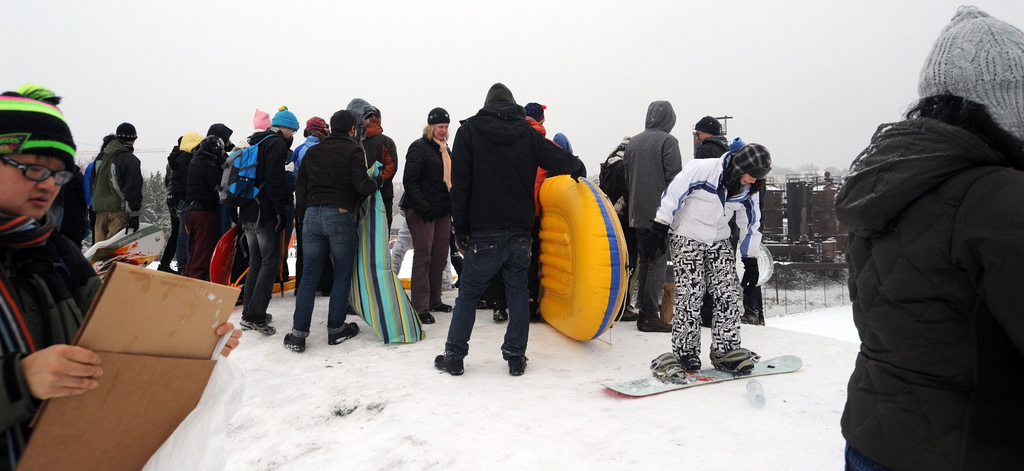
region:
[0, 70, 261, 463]
a boy holding cardboard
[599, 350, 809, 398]
the white snowboard the person is on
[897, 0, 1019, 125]
the gray hat of the person on the right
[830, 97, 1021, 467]
the black coat of the person on the right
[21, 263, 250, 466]
the cardboard the person is holding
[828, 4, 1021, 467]
the person furthest to the right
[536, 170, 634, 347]
the yellow inflatable the person is holding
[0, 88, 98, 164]
the green striped hat of the person on the right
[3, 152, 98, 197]
glasses are worn by the person on the right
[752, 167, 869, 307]
the buildings in the background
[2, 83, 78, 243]
the head of a man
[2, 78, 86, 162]
the hat of a man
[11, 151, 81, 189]
the glasses of a man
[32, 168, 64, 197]
the nose of a man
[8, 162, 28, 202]
the cheek of a man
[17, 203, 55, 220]
the chin of a man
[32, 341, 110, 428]
the right hand of a man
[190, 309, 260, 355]
the left hand of a man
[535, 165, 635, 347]
inflatable raft is yellow and blue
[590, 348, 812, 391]
snowboard is white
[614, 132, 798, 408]
person on a white snowboard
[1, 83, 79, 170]
hat is green, black, and red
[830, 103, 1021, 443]
coat is dark green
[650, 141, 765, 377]
person wearing black and white pants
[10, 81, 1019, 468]
people are all on top of the hill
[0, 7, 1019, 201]
sky is gray and foggy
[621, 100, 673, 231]
coat is gray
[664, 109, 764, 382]
person wearing a white and blue coat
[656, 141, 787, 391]
a person is standing up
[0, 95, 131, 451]
a person is standing up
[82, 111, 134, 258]
a person is standing up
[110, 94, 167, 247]
a person is standing up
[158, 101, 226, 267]
a person is standing up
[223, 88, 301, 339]
a person is standing up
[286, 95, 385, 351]
a person is standing up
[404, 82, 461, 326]
a person is standing up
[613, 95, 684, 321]
a person is standing up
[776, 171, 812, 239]
a building in a city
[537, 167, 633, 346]
yellow and blue blow up sled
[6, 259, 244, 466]
tan piece of cardboard box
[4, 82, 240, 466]
man in black glasses looking at cardboard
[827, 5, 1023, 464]
person in black jacket and gray cap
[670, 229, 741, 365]
pair of black and white patterned pants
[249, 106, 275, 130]
young child wearing pink cap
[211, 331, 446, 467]
deep footprints in the white snow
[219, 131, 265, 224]
blue backpack with black strap and trim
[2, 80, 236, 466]
man looking at cardboard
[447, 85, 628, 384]
man holding yellow sled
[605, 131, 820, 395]
boy on snow board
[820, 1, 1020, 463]
girl wearing knit beanie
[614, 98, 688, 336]
man wearing gray coat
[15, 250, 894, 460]
snow on the ground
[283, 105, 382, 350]
girl wearing black coat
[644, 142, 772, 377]
man wearing white coat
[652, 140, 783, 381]
man wearing plaid hat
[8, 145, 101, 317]
boy wearing eye glasses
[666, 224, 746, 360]
black and white ski pants person is wering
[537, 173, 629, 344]
yellow and blue raft man is holding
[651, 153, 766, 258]
white jacket with black and blue strip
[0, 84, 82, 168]
black cap with green and pink strips